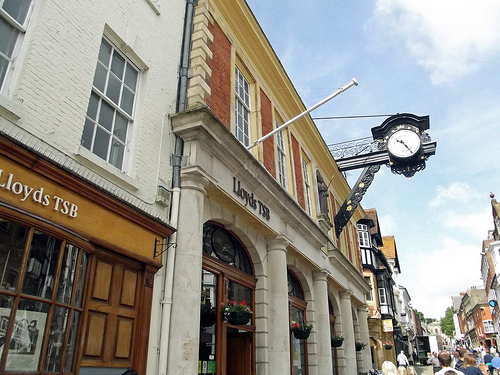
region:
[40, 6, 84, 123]
brick wall painted white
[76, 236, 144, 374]
wood paneled door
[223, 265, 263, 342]
hanging basket with red flowers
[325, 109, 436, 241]
ornate black street clock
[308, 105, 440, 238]
antique street clock mounted to building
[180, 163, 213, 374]
stone pillar on building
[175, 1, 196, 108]
metal downspout for rain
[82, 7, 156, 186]
window with panes of glass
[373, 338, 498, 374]
crowd of people in the street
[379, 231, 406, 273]
steep sloped roof of building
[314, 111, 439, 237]
old fashioned clock on decorative beam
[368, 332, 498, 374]
pedestrians walking down the street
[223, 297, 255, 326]
red flowers in a pot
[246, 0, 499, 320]
white puffy clouds in the blue sky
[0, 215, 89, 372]
vintage advertisement in the store window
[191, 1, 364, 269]
red bricks on the wall between the windows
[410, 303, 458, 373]
green trees at the end of the street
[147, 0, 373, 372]
stone archways on the building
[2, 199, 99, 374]
window frame is dark brown wood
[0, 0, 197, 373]
wrought iron plant hanger on the building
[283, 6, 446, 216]
Picture taken outside.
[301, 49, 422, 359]
Picture taken during the day.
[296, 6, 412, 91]
The sky is bright blue.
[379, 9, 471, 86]
Clouds in the sky.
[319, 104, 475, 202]
A clock on the side of the building.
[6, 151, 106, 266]
Lloyds TSB on the building.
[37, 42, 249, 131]
The building is made of brick.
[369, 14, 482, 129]
The cloud are fluffy.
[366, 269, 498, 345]
People on the street.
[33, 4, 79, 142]
The brick is white in color.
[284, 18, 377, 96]
Sky is blue color.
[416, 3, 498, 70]
Clouds are white color.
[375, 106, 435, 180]
One clock is hanging.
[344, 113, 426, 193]
Clock is black and white color.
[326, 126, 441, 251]
Clock is fixed to the wall.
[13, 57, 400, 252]
windows are attached to the building wall.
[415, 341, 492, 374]
People are walking in the street.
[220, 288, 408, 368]
Flower pots are hanging.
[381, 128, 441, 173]
9.20 is the time shown.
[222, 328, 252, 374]
Door is open.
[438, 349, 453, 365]
the head of a person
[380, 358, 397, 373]
the head of a person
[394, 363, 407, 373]
the head of a person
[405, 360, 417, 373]
the head of a person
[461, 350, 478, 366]
the head of a person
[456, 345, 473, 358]
the head of a person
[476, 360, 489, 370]
the head of a person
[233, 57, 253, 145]
window on a building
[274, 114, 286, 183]
window on a building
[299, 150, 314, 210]
window on a building